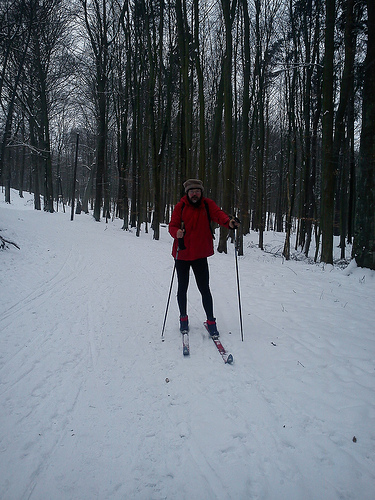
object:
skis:
[177, 317, 196, 363]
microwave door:
[174, 338, 241, 365]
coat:
[164, 195, 233, 259]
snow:
[250, 254, 373, 499]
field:
[4, 185, 374, 498]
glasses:
[186, 189, 203, 194]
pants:
[171, 253, 215, 323]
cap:
[183, 177, 205, 194]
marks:
[0, 242, 98, 499]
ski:
[181, 328, 190, 354]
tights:
[174, 257, 214, 319]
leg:
[192, 262, 213, 317]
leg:
[175, 265, 190, 316]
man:
[161, 177, 236, 334]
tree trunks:
[349, 90, 375, 262]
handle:
[177, 222, 185, 246]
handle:
[229, 216, 242, 239]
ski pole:
[155, 219, 192, 341]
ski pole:
[229, 212, 253, 345]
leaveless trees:
[210, 42, 261, 149]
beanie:
[175, 162, 220, 195]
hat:
[182, 177, 203, 192]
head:
[181, 176, 207, 206]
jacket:
[169, 193, 232, 259]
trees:
[38, 0, 57, 216]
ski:
[201, 318, 234, 365]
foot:
[206, 318, 222, 337]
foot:
[175, 314, 189, 333]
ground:
[0, 182, 373, 497]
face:
[186, 185, 201, 205]